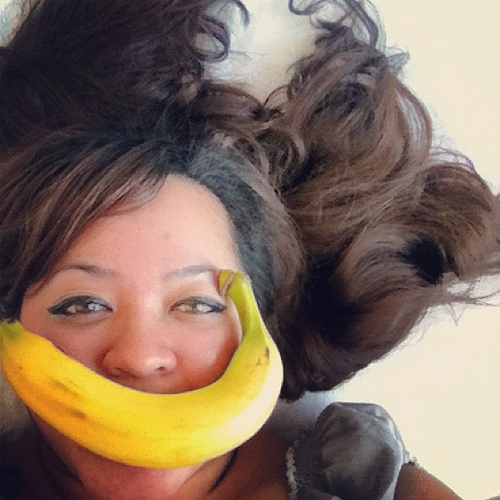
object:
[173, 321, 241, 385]
cheek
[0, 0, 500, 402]
hair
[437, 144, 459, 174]
ground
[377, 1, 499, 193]
sheets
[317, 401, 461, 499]
shoulder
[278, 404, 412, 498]
cloth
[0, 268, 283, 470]
peel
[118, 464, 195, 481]
chin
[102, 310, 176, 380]
nose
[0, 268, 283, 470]
banana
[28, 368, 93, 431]
spot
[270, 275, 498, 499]
wall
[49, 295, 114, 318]
eye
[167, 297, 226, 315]
eye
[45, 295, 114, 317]
makeup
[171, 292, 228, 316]
makeup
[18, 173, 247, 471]
woman's face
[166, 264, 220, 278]
eyebrows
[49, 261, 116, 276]
eyebrows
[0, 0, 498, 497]
surface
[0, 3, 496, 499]
lady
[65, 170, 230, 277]
forehead